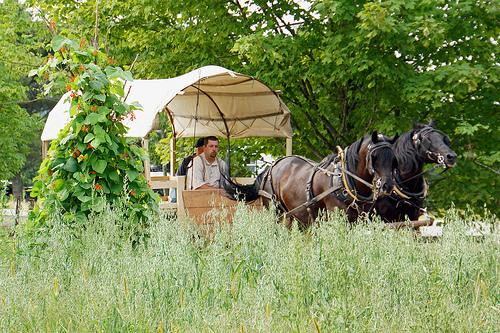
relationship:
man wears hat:
[170, 135, 208, 202] [193, 136, 206, 148]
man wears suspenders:
[185, 136, 228, 189] [199, 154, 223, 185]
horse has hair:
[220, 128, 399, 230] [346, 137, 363, 175]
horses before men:
[221, 121, 459, 233] [185, 136, 228, 189]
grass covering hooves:
[1, 195, 495, 333] [272, 252, 421, 263]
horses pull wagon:
[221, 121, 459, 233] [40, 64, 293, 225]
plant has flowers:
[29, 22, 160, 236] [77, 37, 87, 51]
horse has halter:
[220, 128, 399, 230] [367, 139, 395, 167]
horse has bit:
[220, 128, 399, 230] [371, 176, 383, 193]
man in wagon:
[170, 135, 208, 202] [40, 64, 293, 225]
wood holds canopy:
[285, 136, 292, 157] [41, 64, 295, 147]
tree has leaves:
[231, 1, 426, 162] [358, 4, 397, 33]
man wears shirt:
[185, 136, 228, 189] [188, 152, 231, 189]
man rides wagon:
[170, 135, 208, 202] [40, 64, 293, 225]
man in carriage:
[170, 135, 208, 202] [40, 64, 293, 225]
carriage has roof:
[40, 64, 293, 225] [41, 64, 296, 143]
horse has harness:
[220, 128, 399, 230] [330, 153, 381, 214]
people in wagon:
[171, 137, 228, 198] [40, 64, 293, 225]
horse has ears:
[220, 128, 399, 230] [369, 129, 402, 146]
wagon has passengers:
[40, 64, 293, 225] [185, 136, 228, 189]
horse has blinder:
[220, 128, 399, 230] [367, 150, 400, 174]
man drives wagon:
[185, 136, 228, 189] [40, 64, 293, 225]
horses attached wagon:
[221, 121, 459, 233] [40, 64, 293, 225]